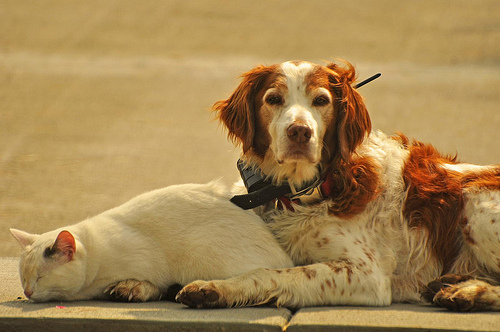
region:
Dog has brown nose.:
[284, 125, 319, 152]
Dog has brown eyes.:
[263, 82, 347, 116]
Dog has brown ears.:
[330, 55, 368, 155]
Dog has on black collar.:
[256, 166, 296, 196]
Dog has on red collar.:
[309, 167, 347, 208]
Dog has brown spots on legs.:
[298, 232, 352, 296]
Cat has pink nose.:
[21, 277, 42, 297]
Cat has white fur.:
[135, 184, 207, 255]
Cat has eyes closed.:
[8, 258, 70, 290]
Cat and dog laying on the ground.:
[146, 152, 362, 293]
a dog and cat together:
[25, 37, 497, 327]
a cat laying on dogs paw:
[2, 57, 499, 327]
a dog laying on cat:
[26, 70, 448, 331]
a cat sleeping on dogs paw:
[17, 54, 477, 330]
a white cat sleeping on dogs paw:
[17, 40, 499, 331]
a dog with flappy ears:
[52, 48, 477, 328]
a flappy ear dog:
[16, 34, 482, 312]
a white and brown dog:
[164, 29, 499, 329]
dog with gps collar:
[141, 48, 499, 330]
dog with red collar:
[147, 38, 497, 330]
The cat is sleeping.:
[3, 180, 308, 312]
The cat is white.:
[4, 179, 310, 319]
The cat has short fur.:
[6, 180, 314, 313]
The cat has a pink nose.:
[11, 285, 42, 303]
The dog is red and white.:
[193, 39, 499, 316]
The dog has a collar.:
[201, 62, 406, 233]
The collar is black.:
[188, 60, 368, 212]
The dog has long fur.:
[194, 50, 494, 302]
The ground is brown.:
[313, 311, 448, 329]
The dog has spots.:
[271, 206, 387, 303]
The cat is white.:
[26, 199, 283, 282]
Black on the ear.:
[31, 230, 70, 262]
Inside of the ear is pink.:
[44, 225, 84, 262]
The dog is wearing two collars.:
[216, 156, 351, 218]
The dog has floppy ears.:
[217, 60, 367, 168]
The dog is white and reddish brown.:
[201, 50, 498, 311]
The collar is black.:
[232, 154, 349, 191]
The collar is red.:
[271, 181, 343, 207]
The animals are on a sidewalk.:
[3, 43, 493, 328]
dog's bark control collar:
[220, 143, 329, 217]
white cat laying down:
[8, 189, 255, 302]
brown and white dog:
[229, 45, 479, 265]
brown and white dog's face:
[267, 72, 346, 173]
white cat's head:
[0, 214, 72, 296]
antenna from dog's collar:
[347, 57, 403, 121]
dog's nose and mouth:
[280, 112, 314, 165]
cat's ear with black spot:
[37, 196, 84, 272]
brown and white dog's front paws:
[116, 248, 241, 309]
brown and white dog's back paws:
[426, 250, 494, 321]